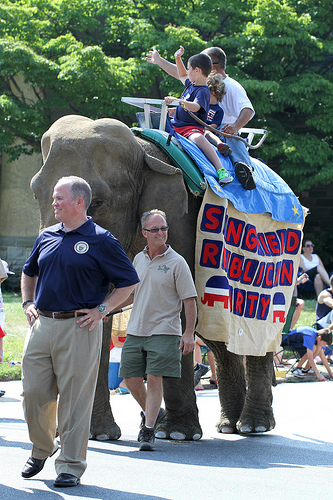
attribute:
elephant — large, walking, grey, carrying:
[35, 112, 313, 453]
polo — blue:
[17, 214, 138, 319]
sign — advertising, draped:
[187, 177, 312, 358]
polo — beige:
[119, 245, 200, 340]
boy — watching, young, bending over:
[282, 325, 332, 378]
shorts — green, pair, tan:
[116, 332, 183, 380]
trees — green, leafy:
[5, 0, 332, 226]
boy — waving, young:
[159, 44, 236, 181]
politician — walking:
[19, 174, 146, 485]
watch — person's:
[97, 301, 112, 317]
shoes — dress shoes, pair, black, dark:
[23, 443, 90, 488]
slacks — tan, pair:
[22, 314, 104, 477]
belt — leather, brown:
[37, 307, 90, 319]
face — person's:
[146, 214, 171, 249]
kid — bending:
[281, 326, 332, 381]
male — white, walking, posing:
[17, 175, 144, 489]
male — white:
[123, 206, 202, 451]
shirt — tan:
[120, 244, 199, 340]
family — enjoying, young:
[146, 38, 275, 189]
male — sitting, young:
[163, 36, 236, 185]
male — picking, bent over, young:
[280, 317, 332, 381]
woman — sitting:
[295, 236, 332, 309]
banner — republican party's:
[180, 191, 312, 364]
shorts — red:
[171, 120, 204, 138]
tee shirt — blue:
[169, 75, 220, 128]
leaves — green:
[4, 0, 331, 201]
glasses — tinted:
[149, 221, 172, 230]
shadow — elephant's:
[2, 397, 333, 489]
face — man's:
[50, 177, 93, 224]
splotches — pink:
[61, 201, 82, 217]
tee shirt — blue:
[280, 328, 324, 351]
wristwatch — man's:
[100, 301, 108, 319]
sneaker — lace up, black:
[138, 424, 157, 454]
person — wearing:
[298, 239, 332, 306]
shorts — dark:
[299, 267, 320, 297]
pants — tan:
[19, 314, 114, 473]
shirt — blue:
[19, 214, 145, 319]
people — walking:
[17, 170, 205, 490]